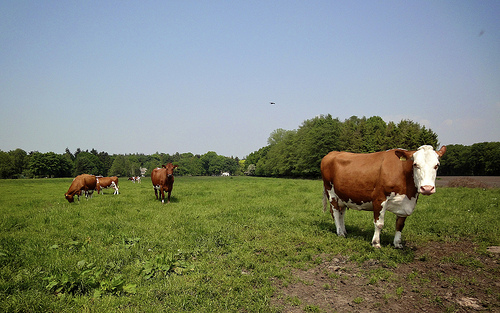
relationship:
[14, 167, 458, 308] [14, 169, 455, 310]
field of grass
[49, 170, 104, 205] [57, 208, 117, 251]
cow in grass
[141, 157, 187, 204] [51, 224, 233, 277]
cow walking grass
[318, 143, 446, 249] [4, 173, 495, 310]
cow standing on ground